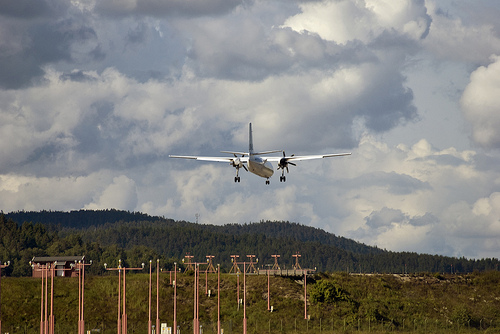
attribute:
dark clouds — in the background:
[3, 3, 217, 99]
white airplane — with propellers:
[166, 126, 350, 186]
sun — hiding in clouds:
[281, 0, 420, 108]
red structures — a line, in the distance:
[179, 249, 307, 270]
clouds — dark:
[160, 32, 412, 158]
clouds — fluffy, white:
[273, 5, 493, 242]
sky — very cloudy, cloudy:
[1, 0, 495, 260]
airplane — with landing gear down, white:
[168, 120, 351, 183]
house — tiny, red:
[32, 253, 92, 276]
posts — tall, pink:
[36, 260, 58, 330]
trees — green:
[119, 223, 158, 243]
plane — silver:
[166, 121, 352, 182]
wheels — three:
[229, 173, 288, 183]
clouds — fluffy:
[1, 1, 500, 259]